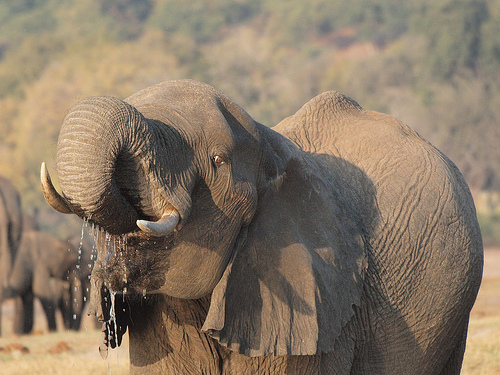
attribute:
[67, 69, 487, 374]
elephant — wrinkled, drinking, big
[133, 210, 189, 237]
tusk — white, ivory, bent, curved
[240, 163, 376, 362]
ear — big, gray, large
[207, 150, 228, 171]
eye — brown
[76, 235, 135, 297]
water — falling, dripping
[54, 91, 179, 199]
trunk — grey, curved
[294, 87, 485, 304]
skin — grey, wrinkled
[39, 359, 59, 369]
grass — dry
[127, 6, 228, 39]
trees — green